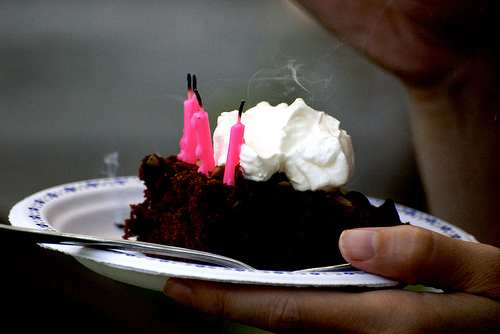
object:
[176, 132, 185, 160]
melted wax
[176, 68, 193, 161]
candle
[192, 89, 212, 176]
candle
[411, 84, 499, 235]
neck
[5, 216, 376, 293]
silver fork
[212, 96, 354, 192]
whipped cream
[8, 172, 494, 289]
paper plate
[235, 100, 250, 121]
string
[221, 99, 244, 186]
candle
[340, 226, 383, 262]
fingernail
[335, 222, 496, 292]
thumb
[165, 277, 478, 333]
finger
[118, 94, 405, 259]
cake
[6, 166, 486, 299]
plate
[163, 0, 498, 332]
person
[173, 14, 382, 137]
smoke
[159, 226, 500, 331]
hand